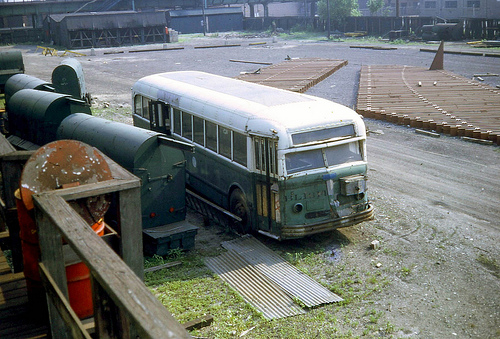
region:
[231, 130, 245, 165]
glass window on bus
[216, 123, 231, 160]
glass window on bus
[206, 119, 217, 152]
glass window on bus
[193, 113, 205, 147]
glass window on bus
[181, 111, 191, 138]
glass window on bus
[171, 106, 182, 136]
glass window on bus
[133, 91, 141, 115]
glass window on bus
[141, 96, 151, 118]
glass window on bus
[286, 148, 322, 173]
glass window on bus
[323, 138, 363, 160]
glass window on bus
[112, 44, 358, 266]
an old worn out bus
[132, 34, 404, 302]
an old worn out bus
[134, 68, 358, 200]
bus' roof is white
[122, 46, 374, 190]
bus' roof is white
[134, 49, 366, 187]
bus' roof is white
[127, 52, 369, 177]
bus' roof is white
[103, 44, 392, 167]
bus' roof is white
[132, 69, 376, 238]
old green and white bus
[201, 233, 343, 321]
gray corrugated sheet metal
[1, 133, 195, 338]
brown faded wooden railing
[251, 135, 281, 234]
old green and white bus door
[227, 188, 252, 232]
old black bus tire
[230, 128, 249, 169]
white framed bus window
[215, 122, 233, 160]
white framed bus window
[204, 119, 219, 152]
white framed bus window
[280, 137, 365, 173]
white framed bus window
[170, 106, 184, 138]
white framed bus window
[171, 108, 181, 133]
glass window on bus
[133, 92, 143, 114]
glass window on bus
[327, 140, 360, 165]
glass window on bus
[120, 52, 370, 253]
Bus in the forefront.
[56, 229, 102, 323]
Red barrel under wood frame.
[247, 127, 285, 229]
Door on the bus.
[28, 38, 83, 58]
Yellow wood frames in the background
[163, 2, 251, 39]
Building in the background.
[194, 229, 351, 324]
metal on the ground.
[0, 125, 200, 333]
Wood railing in the forefront.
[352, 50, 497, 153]
Wood platform on the ground.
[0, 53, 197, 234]
Metal tanks on the ground.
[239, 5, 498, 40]
Wooden fence in the background.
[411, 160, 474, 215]
The track is dirt.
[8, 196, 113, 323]
The can is orange.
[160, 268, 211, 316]
The grass is green.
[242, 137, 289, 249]
The door is closed.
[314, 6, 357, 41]
A tree is in the back.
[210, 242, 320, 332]
A fence is on the ground.